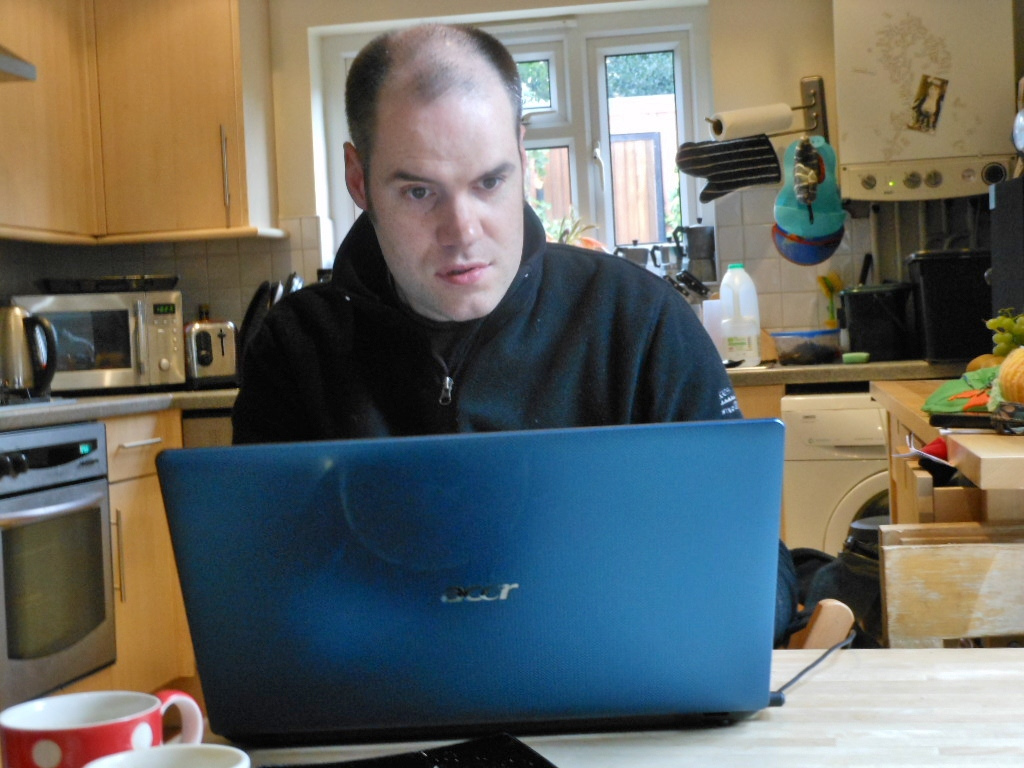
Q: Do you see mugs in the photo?
A: Yes, there is a mug.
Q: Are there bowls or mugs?
A: Yes, there is a mug.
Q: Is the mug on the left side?
A: Yes, the mug is on the left of the image.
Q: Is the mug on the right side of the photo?
A: No, the mug is on the left of the image.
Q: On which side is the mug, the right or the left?
A: The mug is on the left of the image.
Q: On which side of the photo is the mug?
A: The mug is on the left of the image.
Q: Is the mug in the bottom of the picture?
A: Yes, the mug is in the bottom of the image.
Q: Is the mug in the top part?
A: No, the mug is in the bottom of the image.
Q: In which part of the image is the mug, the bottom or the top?
A: The mug is in the bottom of the image.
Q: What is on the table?
A: The mug is on the table.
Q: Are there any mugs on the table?
A: Yes, there is a mug on the table.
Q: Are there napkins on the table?
A: No, there is a mug on the table.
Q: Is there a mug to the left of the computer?
A: Yes, there is a mug to the left of the computer.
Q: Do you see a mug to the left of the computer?
A: Yes, there is a mug to the left of the computer.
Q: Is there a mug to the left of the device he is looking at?
A: Yes, there is a mug to the left of the computer.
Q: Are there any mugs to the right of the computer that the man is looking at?
A: No, the mug is to the left of the computer.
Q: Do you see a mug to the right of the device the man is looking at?
A: No, the mug is to the left of the computer.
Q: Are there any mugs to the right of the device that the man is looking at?
A: No, the mug is to the left of the computer.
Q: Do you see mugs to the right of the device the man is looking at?
A: No, the mug is to the left of the computer.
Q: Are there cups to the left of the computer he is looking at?
A: No, there is a mug to the left of the computer.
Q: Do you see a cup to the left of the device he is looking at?
A: No, there is a mug to the left of the computer.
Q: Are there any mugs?
A: Yes, there is a mug.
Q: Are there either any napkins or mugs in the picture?
A: Yes, there is a mug.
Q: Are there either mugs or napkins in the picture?
A: Yes, there is a mug.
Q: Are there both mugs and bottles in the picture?
A: Yes, there are both a mug and a bottle.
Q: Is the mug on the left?
A: Yes, the mug is on the left of the image.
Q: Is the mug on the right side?
A: No, the mug is on the left of the image.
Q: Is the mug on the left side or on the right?
A: The mug is on the left of the image.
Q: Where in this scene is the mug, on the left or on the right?
A: The mug is on the left of the image.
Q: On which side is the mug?
A: The mug is on the left of the image.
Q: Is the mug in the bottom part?
A: Yes, the mug is in the bottom of the image.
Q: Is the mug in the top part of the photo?
A: No, the mug is in the bottom of the image.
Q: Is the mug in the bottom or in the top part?
A: The mug is in the bottom of the image.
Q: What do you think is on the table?
A: The mug is on the table.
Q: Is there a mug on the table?
A: Yes, there is a mug on the table.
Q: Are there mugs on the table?
A: Yes, there is a mug on the table.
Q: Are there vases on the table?
A: No, there is a mug on the table.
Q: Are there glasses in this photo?
A: No, there are no glasses.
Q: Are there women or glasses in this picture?
A: No, there are no glasses or women.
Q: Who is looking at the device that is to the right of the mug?
A: The man is looking at the computer.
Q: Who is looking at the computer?
A: The man is looking at the computer.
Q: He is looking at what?
A: The man is looking at the computer.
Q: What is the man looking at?
A: The man is looking at the computer.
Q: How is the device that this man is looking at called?
A: The device is a computer.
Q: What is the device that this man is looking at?
A: The device is a computer.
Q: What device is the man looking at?
A: The man is looking at the computer.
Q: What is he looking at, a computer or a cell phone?
A: The man is looking at a computer.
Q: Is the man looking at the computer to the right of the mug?
A: Yes, the man is looking at the computer.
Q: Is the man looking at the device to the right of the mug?
A: Yes, the man is looking at the computer.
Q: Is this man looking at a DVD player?
A: No, the man is looking at the computer.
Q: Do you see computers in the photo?
A: Yes, there is a computer.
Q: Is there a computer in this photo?
A: Yes, there is a computer.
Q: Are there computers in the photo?
A: Yes, there is a computer.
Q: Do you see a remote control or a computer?
A: Yes, there is a computer.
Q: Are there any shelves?
A: No, there are no shelves.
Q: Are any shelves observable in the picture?
A: No, there are no shelves.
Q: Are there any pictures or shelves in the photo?
A: No, there are no shelves or pictures.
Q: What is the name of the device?
A: The device is a computer.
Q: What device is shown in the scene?
A: The device is a computer.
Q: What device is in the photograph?
A: The device is a computer.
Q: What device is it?
A: The device is a computer.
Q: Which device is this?
A: This is a computer.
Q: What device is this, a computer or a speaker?
A: This is a computer.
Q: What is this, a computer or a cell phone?
A: This is a computer.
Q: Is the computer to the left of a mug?
A: No, the computer is to the right of a mug.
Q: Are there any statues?
A: No, there are no statues.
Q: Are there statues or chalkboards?
A: No, there are no statues or chalkboards.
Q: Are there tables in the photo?
A: Yes, there is a table.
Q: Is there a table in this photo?
A: Yes, there is a table.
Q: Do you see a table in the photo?
A: Yes, there is a table.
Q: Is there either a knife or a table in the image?
A: Yes, there is a table.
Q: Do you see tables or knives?
A: Yes, there is a table.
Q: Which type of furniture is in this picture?
A: The furniture is a table.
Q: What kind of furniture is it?
A: The piece of furniture is a table.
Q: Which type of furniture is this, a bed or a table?
A: This is a table.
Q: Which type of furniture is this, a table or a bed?
A: This is a table.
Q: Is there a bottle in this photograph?
A: Yes, there is a bottle.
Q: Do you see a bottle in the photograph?
A: Yes, there is a bottle.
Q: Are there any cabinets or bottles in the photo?
A: Yes, there is a bottle.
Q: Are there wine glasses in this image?
A: No, there are no wine glasses.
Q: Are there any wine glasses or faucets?
A: No, there are no wine glasses or faucets.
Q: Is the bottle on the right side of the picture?
A: Yes, the bottle is on the right of the image.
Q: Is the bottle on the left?
A: No, the bottle is on the right of the image.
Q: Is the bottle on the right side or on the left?
A: The bottle is on the right of the image.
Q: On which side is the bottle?
A: The bottle is on the right of the image.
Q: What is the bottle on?
A: The bottle is on the counter.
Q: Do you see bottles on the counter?
A: Yes, there is a bottle on the counter.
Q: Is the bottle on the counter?
A: Yes, the bottle is on the counter.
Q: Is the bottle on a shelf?
A: No, the bottle is on the counter.